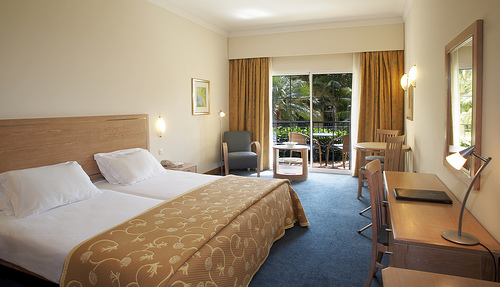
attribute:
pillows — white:
[3, 139, 165, 196]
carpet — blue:
[218, 163, 385, 283]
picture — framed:
[197, 87, 207, 107]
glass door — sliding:
[276, 72, 351, 169]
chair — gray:
[219, 126, 264, 179]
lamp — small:
[436, 142, 496, 249]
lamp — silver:
[433, 146, 499, 246]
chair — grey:
[213, 119, 268, 174]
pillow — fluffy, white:
[94, 146, 164, 184]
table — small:
[272, 143, 308, 180]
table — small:
[352, 141, 410, 179]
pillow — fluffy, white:
[1, 158, 101, 221]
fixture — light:
[398, 62, 423, 87]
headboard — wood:
[6, 115, 134, 152]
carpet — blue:
[291, 187, 365, 282]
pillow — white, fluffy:
[81, 93, 187, 218]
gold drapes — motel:
[362, 59, 402, 126]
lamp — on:
[443, 135, 487, 177]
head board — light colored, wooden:
[1, 109, 153, 183]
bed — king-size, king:
[2, 113, 291, 285]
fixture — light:
[394, 60, 436, 126]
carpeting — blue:
[301, 177, 356, 281]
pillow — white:
[94, 151, 166, 174]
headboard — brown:
[5, 116, 194, 158]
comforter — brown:
[49, 180, 315, 284]